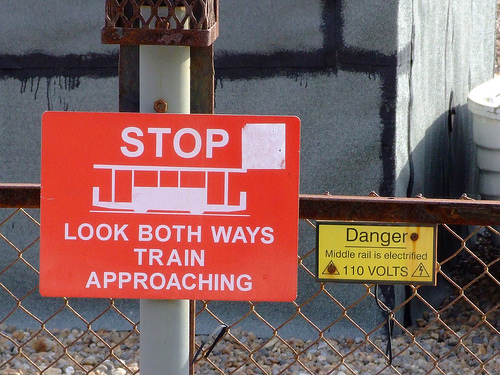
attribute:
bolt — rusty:
[153, 93, 167, 115]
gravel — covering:
[2, 261, 495, 373]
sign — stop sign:
[28, 104, 318, 321]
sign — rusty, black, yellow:
[315, 218, 437, 285]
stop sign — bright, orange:
[39, 108, 301, 302]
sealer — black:
[3, 5, 427, 319]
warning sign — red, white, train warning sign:
[36, 109, 299, 301]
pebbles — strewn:
[233, 334, 338, 364]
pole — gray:
[136, 43, 189, 373]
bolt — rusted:
[398, 229, 430, 247]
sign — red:
[37, 109, 297, 299]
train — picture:
[128, 184, 207, 221]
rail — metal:
[303, 193, 499, 228]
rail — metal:
[1, 179, 42, 211]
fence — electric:
[1, 183, 499, 370]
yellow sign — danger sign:
[313, 220, 437, 287]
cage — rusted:
[1, 170, 498, 375]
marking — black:
[341, 258, 408, 293]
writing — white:
[76, 269, 251, 309]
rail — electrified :
[0, 180, 499, 227]